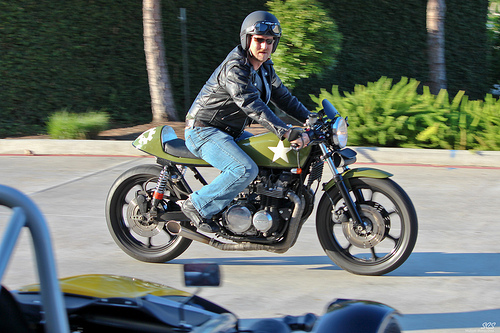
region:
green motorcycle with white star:
[105, 97, 419, 279]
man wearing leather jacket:
[177, 5, 321, 240]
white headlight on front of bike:
[333, 114, 350, 153]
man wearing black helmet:
[233, 10, 285, 53]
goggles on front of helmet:
[247, 19, 286, 41]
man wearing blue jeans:
[180, 122, 257, 219]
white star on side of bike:
[263, 138, 295, 169]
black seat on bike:
[163, 135, 207, 159]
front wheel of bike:
[312, 170, 419, 275]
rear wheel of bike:
[103, 161, 195, 262]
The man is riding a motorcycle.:
[96, 7, 432, 283]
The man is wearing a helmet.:
[173, 6, 334, 252]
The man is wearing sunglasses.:
[183, 8, 323, 246]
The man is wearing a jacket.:
[170, 10, 333, 245]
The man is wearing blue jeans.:
[171, 5, 331, 257]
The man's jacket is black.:
[162, 0, 337, 240]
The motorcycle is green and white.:
[95, 5, 452, 285]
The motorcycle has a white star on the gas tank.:
[105, 76, 425, 276]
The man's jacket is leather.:
[171, 7, 349, 252]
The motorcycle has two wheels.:
[84, 2, 429, 287]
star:
[260, 136, 297, 167]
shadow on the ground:
[424, 234, 496, 280]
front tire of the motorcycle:
[322, 192, 409, 268]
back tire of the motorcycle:
[97, 173, 173, 261]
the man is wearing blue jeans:
[197, 136, 246, 168]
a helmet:
[240, 10, 275, 24]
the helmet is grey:
[245, 9, 272, 19]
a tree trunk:
[141, 25, 183, 115]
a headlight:
[330, 115, 346, 144]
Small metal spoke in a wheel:
[380, 206, 397, 225]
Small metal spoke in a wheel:
[385, 231, 402, 246]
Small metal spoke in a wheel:
[361, 243, 374, 275]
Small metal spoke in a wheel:
[337, 240, 364, 259]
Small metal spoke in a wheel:
[329, 212, 346, 228]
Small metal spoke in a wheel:
[132, 179, 152, 190]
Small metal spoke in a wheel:
[118, 200, 132, 211]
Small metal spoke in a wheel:
[122, 223, 132, 235]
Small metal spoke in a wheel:
[139, 233, 154, 255]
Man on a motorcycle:
[80, 23, 417, 279]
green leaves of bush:
[309, 81, 496, 144]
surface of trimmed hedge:
[2, 3, 494, 125]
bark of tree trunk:
[142, 2, 172, 122]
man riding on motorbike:
[104, 9, 419, 274]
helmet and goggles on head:
[239, 9, 283, 53]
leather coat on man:
[185, 47, 309, 140]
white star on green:
[269, 137, 296, 164]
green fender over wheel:
[317, 166, 420, 276]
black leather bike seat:
[161, 135, 194, 158]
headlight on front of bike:
[333, 119, 347, 149]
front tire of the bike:
[303, 163, 436, 277]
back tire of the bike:
[96, 175, 203, 271]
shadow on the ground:
[431, 225, 488, 293]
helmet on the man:
[220, 6, 300, 41]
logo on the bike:
[260, 133, 301, 174]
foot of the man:
[172, 186, 215, 229]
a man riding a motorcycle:
[105, 8, 421, 276]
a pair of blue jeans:
[183, 127, 258, 219]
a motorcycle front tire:
[316, 174, 418, 279]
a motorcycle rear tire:
[104, 164, 196, 264]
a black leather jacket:
[184, 45, 311, 135]